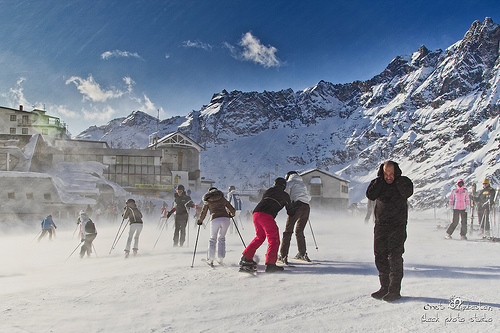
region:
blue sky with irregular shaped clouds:
[10, 5, 485, 126]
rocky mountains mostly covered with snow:
[77, 12, 493, 197]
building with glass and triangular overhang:
[100, 95, 200, 225]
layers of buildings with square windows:
[0, 101, 51, 212]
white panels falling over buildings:
[45, 140, 121, 205]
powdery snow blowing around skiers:
[25, 160, 365, 280]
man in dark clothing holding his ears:
[360, 157, 415, 302]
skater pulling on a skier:
[230, 162, 320, 269]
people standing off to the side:
[441, 170, 491, 240]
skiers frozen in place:
[56, 180, 193, 261]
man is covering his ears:
[366, 160, 415, 302]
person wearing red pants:
[238, 175, 293, 273]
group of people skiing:
[39, 170, 497, 276]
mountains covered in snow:
[72, 25, 498, 211]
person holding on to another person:
[236, 170, 332, 270]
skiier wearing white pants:
[195, 183, 239, 271]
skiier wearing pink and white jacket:
[443, 174, 470, 241]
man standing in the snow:
[368, 153, 417, 304]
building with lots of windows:
[0, 97, 203, 219]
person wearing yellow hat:
[471, 175, 498, 238]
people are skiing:
[54, 181, 339, 291]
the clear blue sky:
[322, 13, 413, 38]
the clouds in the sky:
[153, 15, 287, 62]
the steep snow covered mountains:
[187, 17, 498, 156]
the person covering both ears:
[355, 154, 417, 303]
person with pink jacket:
[444, 178, 471, 215]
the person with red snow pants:
[241, 213, 286, 265]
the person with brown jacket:
[197, 190, 244, 217]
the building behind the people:
[15, 108, 221, 191]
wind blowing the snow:
[9, 238, 100, 314]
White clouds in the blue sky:
[1, 0, 499, 136]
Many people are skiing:
[31, 158, 498, 270]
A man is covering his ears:
[364, 156, 418, 203]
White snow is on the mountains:
[77, 13, 498, 210]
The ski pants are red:
[239, 206, 282, 266]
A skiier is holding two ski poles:
[186, 180, 252, 269]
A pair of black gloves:
[372, 158, 404, 181]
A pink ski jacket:
[448, 177, 471, 212]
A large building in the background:
[3, 102, 203, 225]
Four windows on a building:
[8, 107, 33, 139]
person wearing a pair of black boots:
[347, 150, 431, 320]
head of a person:
[365, 155, 407, 182]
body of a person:
[370, 203, 418, 246]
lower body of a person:
[363, 227, 409, 304]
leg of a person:
[359, 234, 424, 306]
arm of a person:
[395, 161, 418, 198]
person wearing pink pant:
[215, 145, 298, 267]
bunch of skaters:
[25, 161, 447, 301]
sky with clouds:
[152, 35, 308, 75]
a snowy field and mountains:
[85, 68, 498, 194]